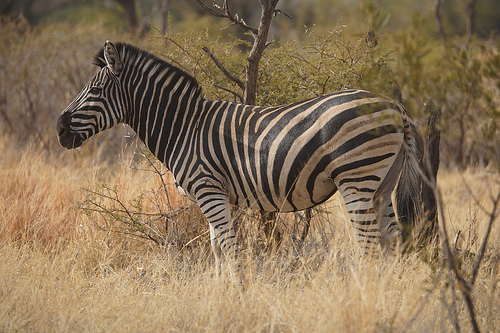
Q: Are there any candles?
A: No, there are no candles.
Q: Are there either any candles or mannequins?
A: No, there are no candles or mannequins.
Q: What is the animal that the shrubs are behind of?
A: The animal is a zebra.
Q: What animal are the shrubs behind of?
A: The shrubs are behind the zebra.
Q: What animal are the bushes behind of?
A: The shrubs are behind the zebra.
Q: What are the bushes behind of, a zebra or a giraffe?
A: The bushes are behind a zebra.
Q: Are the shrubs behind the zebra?
A: Yes, the shrubs are behind the zebra.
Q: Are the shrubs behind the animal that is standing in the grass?
A: Yes, the shrubs are behind the zebra.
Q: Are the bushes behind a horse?
A: No, the bushes are behind the zebra.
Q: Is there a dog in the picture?
A: No, there are no dogs.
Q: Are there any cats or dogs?
A: No, there are no dogs or cats.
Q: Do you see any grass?
A: Yes, there is grass.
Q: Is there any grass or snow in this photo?
A: Yes, there is grass.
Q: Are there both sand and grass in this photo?
A: No, there is grass but no sand.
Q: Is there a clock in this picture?
A: No, there are no clocks.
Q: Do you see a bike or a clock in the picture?
A: No, there are no clocks or bikes.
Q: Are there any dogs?
A: No, there are no dogs.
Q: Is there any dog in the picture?
A: No, there are no dogs.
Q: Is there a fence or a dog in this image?
A: No, there are no dogs or fences.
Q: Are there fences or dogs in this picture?
A: No, there are no dogs or fences.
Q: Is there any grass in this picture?
A: Yes, there is grass.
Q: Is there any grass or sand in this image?
A: Yes, there is grass.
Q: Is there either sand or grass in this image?
A: Yes, there is grass.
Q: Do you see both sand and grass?
A: No, there is grass but no sand.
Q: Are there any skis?
A: No, there are no skis.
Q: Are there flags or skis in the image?
A: No, there are no skis or flags.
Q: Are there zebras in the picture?
A: Yes, there is a zebra.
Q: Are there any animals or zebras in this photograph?
A: Yes, there is a zebra.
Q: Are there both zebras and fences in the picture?
A: No, there is a zebra but no fences.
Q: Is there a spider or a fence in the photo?
A: No, there are no fences or spiders.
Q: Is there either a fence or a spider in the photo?
A: No, there are no fences or spiders.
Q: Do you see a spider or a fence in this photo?
A: No, there are no fences or spiders.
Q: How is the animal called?
A: The animal is a zebra.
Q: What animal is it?
A: The animal is a zebra.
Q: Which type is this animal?
A: That is a zebra.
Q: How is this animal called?
A: That is a zebra.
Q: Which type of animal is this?
A: That is a zebra.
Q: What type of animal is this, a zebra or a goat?
A: That is a zebra.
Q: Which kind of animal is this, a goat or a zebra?
A: That is a zebra.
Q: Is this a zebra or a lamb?
A: This is a zebra.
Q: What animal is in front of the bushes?
A: The zebra is in front of the bushes.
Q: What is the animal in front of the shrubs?
A: The animal is a zebra.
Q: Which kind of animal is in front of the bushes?
A: The animal is a zebra.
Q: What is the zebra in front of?
A: The zebra is in front of the bushes.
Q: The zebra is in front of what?
A: The zebra is in front of the bushes.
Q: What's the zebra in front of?
A: The zebra is in front of the bushes.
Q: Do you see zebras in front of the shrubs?
A: Yes, there is a zebra in front of the shrubs.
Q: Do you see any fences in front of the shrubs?
A: No, there is a zebra in front of the shrubs.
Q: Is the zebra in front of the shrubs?
A: Yes, the zebra is in front of the shrubs.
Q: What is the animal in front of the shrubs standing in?
A: The zebra is standing in the grass.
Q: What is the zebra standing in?
A: The zebra is standing in the grass.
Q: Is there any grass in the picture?
A: Yes, there is grass.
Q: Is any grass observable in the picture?
A: Yes, there is grass.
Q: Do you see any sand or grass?
A: Yes, there is grass.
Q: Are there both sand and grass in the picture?
A: No, there is grass but no sand.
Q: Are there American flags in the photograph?
A: No, there are no American flags.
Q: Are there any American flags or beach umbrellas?
A: No, there are no American flags or beach umbrellas.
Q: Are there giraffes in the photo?
A: No, there are no giraffes.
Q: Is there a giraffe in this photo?
A: No, there are no giraffes.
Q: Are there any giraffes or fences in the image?
A: No, there are no giraffes or fences.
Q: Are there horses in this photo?
A: No, there are no horses.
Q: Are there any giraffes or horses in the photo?
A: No, there are no horses or giraffes.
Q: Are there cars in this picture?
A: No, there are no cars.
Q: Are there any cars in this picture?
A: No, there are no cars.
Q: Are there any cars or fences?
A: No, there are no cars or fences.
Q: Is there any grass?
A: Yes, there is grass.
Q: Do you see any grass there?
A: Yes, there is grass.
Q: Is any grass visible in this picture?
A: Yes, there is grass.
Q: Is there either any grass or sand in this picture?
A: Yes, there is grass.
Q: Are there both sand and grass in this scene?
A: No, there is grass but no sand.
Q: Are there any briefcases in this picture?
A: No, there are no briefcases.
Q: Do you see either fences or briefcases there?
A: No, there are no briefcases or fences.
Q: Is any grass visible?
A: Yes, there is grass.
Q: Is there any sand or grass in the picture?
A: Yes, there is grass.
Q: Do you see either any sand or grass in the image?
A: Yes, there is grass.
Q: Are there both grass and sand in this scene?
A: No, there is grass but no sand.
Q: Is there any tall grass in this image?
A: Yes, there is tall grass.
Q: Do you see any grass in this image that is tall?
A: Yes, there is grass that is tall.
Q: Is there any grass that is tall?
A: Yes, there is grass that is tall.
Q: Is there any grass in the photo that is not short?
A: Yes, there is tall grass.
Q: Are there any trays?
A: No, there are no trays.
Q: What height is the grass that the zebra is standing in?
A: The grass is tall.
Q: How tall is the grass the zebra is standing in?
A: The grass is tall.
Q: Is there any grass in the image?
A: Yes, there is grass.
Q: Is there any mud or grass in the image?
A: Yes, there is grass.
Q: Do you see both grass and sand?
A: No, there is grass but no sand.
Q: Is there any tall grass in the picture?
A: Yes, there is tall grass.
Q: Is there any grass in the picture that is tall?
A: Yes, there is grass that is tall.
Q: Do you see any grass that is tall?
A: Yes, there is grass that is tall.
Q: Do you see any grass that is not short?
A: Yes, there is tall grass.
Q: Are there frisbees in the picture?
A: No, there are no frisbees.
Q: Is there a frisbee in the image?
A: No, there are no frisbees.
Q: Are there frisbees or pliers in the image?
A: No, there are no frisbees or pliers.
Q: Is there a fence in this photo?
A: No, there are no fences.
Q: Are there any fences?
A: No, there are no fences.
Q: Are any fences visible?
A: No, there are no fences.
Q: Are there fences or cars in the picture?
A: No, there are no fences or cars.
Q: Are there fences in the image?
A: No, there are no fences.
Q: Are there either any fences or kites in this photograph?
A: No, there are no fences or kites.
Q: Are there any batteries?
A: No, there are no batteries.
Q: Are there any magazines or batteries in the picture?
A: No, there are no batteries or magazines.